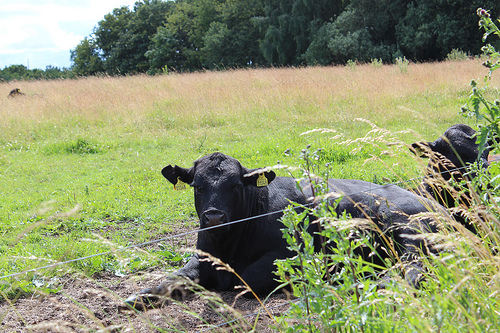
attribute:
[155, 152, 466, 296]
cow — laying, trying, black, large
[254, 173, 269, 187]
tag — yellow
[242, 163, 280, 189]
ear — torn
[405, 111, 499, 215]
cow — hidden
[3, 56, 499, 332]
pasture — grassy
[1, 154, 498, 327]
fence — wire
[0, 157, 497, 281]
wire — silver, small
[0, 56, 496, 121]
grass — dry, green, tall, brown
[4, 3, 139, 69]
sky — blue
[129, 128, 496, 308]
cows — lying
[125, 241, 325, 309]
legs — folded